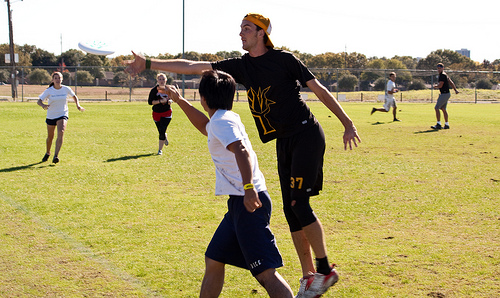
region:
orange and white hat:
[237, 4, 293, 46]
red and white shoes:
[282, 255, 356, 295]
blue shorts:
[200, 174, 294, 293]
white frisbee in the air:
[58, 19, 138, 81]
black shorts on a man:
[270, 95, 354, 235]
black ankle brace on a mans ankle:
[305, 245, 340, 285]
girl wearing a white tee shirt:
[29, 70, 88, 127]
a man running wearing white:
[361, 56, 409, 132]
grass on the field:
[368, 150, 444, 222]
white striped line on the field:
[41, 199, 91, 294]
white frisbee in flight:
[71, 28, 124, 61]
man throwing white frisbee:
[9, 7, 389, 228]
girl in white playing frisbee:
[21, 57, 101, 184]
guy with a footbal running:
[349, 56, 414, 133]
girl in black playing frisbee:
[134, 74, 186, 156]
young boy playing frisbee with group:
[136, 73, 307, 296]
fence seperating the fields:
[3, 70, 496, 110]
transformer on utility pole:
[4, 40, 26, 69]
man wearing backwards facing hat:
[202, 13, 297, 53]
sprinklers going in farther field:
[308, 62, 493, 97]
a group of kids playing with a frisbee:
[9, 11, 484, 291]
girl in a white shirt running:
[31, 68, 81, 165]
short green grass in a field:
[0, 181, 181, 293]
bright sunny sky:
[285, 5, 499, 48]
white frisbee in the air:
[70, 32, 120, 62]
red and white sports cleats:
[288, 261, 355, 296]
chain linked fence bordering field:
[1, 62, 133, 97]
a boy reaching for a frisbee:
[181, 70, 281, 296]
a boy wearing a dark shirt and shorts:
[426, 57, 461, 134]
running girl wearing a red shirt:
[143, 74, 181, 152]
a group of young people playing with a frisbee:
[25, 10, 489, 283]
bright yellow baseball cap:
[243, 10, 280, 48]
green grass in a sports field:
[366, 147, 490, 287]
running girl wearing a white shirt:
[28, 64, 83, 164]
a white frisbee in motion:
[73, 32, 117, 64]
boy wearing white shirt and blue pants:
[191, 69, 268, 295]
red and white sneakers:
[289, 258, 345, 295]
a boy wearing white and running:
[366, 66, 406, 126]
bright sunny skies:
[11, 1, 228, 44]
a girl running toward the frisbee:
[144, 72, 185, 154]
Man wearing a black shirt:
[208, 3, 383, 271]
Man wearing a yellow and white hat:
[228, 4, 299, 71]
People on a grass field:
[18, 18, 490, 283]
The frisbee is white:
[68, 28, 148, 89]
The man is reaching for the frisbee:
[81, 11, 364, 271]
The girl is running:
[26, 57, 113, 197]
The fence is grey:
[8, 40, 481, 115]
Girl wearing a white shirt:
[33, 61, 88, 174]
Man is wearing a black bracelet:
[121, 48, 171, 79]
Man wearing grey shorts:
[418, 53, 470, 146]